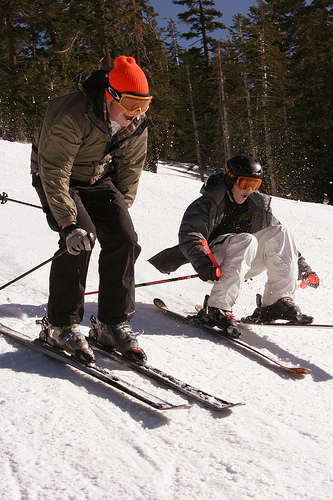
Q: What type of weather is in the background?
A: It is clear.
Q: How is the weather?
A: It is clear.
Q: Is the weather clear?
A: Yes, it is clear.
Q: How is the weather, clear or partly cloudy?
A: It is clear.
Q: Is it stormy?
A: No, it is clear.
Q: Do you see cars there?
A: No, there are no cars.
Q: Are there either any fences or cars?
A: No, there are no cars or fences.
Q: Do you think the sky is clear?
A: Yes, the sky is clear.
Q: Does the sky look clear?
A: Yes, the sky is clear.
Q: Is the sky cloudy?
A: No, the sky is clear.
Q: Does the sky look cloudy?
A: No, the sky is clear.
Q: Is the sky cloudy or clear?
A: The sky is clear.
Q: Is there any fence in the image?
A: No, there are no fences.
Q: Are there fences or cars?
A: No, there are no fences or cars.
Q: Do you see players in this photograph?
A: No, there are no players.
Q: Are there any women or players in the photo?
A: No, there are no players or women.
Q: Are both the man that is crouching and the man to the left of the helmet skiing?
A: Yes, both the man and the man are skiing.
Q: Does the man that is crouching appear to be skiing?
A: Yes, the man is skiing.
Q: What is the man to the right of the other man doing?
A: The man is skiing.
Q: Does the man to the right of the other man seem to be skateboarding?
A: No, the man is skiing.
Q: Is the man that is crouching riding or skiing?
A: The man is skiing.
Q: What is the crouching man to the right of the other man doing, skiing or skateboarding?
A: The man is skiing.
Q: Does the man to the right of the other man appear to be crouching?
A: Yes, the man is crouching.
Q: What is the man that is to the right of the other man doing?
A: The man is crouching.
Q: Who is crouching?
A: The man is crouching.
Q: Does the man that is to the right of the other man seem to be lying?
A: No, the man is crouching.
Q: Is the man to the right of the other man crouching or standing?
A: The man is crouching.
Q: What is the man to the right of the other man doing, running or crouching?
A: The man is crouching.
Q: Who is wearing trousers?
A: The man is wearing trousers.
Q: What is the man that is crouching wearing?
A: The man is wearing pants.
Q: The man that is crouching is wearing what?
A: The man is wearing pants.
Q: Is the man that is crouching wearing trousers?
A: Yes, the man is wearing trousers.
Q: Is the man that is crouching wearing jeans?
A: No, the man is wearing trousers.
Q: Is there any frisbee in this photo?
A: No, there are no frisbees.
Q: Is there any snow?
A: Yes, there is snow.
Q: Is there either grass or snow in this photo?
A: Yes, there is snow.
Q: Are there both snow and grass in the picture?
A: No, there is snow but no grass.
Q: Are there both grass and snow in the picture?
A: No, there is snow but no grass.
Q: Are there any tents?
A: No, there are no tents.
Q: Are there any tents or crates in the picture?
A: No, there are no tents or crates.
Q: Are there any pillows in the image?
A: No, there are no pillows.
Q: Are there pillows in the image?
A: No, there are no pillows.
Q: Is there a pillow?
A: No, there are no pillows.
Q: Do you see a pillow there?
A: No, there are no pillows.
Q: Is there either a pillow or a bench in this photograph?
A: No, there are no pillows or benches.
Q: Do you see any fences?
A: No, there are no fences.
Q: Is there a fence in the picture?
A: No, there are no fences.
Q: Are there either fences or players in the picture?
A: No, there are no fences or players.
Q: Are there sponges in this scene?
A: No, there are no sponges.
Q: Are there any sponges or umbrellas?
A: No, there are no sponges or umbrellas.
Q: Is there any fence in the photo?
A: No, there are no fences.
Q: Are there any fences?
A: No, there are no fences.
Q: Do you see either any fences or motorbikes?
A: No, there are no fences or motorbikes.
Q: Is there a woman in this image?
A: No, there are no women.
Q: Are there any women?
A: No, there are no women.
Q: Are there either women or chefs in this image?
A: No, there are no women or chefs.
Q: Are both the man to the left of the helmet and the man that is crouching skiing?
A: Yes, both the man and the man are skiing.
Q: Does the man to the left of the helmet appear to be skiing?
A: Yes, the man is skiing.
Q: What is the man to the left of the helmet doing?
A: The man is skiing.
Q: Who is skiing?
A: The man is skiing.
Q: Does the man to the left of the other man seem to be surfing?
A: No, the man is skiing.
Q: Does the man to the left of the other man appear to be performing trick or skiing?
A: The man is skiing.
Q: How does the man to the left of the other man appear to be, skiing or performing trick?
A: The man is skiing.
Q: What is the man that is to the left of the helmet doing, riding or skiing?
A: The man is skiing.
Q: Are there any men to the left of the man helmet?
A: Yes, there is a man to the left of the helmet.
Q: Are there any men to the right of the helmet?
A: No, the man is to the left of the helmet.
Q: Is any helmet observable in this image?
A: Yes, there is a helmet.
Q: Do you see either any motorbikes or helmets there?
A: Yes, there is a helmet.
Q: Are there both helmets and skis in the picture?
A: Yes, there are both a helmet and skis.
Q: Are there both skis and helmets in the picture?
A: Yes, there are both a helmet and skis.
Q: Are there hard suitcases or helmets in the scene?
A: Yes, there is a hard helmet.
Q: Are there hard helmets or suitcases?
A: Yes, there is a hard helmet.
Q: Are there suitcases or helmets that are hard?
A: Yes, the helmet is hard.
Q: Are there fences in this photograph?
A: No, there are no fences.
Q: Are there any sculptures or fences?
A: No, there are no fences or sculptures.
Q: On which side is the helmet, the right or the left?
A: The helmet is on the right of the image.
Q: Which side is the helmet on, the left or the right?
A: The helmet is on the right of the image.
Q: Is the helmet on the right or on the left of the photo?
A: The helmet is on the right of the image.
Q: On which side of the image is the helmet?
A: The helmet is on the right of the image.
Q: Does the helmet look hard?
A: Yes, the helmet is hard.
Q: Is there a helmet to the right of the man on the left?
A: Yes, there is a helmet to the right of the man.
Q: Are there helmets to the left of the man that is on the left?
A: No, the helmet is to the right of the man.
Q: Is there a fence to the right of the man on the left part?
A: No, there is a helmet to the right of the man.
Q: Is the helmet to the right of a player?
A: No, the helmet is to the right of a man.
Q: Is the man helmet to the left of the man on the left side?
A: No, the helmet is to the right of the man.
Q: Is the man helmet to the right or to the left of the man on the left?
A: The helmet is to the right of the man.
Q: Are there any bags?
A: No, there are no bags.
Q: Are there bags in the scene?
A: No, there are no bags.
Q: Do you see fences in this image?
A: No, there are no fences.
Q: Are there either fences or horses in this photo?
A: No, there are no fences or horses.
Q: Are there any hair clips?
A: No, there are no hair clips.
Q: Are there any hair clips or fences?
A: No, there are no hair clips or fences.